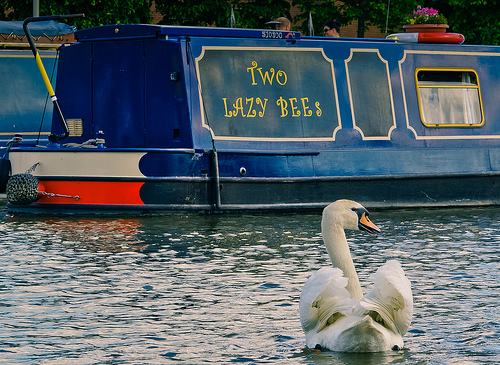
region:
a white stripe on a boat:
[5, 145, 157, 171]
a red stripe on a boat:
[14, 179, 155, 202]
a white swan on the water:
[267, 187, 428, 354]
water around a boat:
[1, 214, 498, 362]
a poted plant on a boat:
[402, 7, 448, 32]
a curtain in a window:
[420, 79, 493, 124]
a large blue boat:
[5, 13, 498, 215]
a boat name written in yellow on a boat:
[216, 57, 329, 128]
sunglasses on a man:
[320, 26, 331, 33]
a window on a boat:
[409, 62, 489, 133]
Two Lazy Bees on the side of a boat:
[216, 57, 322, 131]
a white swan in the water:
[281, 182, 417, 354]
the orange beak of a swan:
[358, 210, 378, 235]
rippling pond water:
[24, 235, 303, 363]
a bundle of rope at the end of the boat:
[6, 154, 58, 211]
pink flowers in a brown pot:
[393, 2, 453, 36]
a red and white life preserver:
[393, 27, 465, 44]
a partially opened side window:
[413, 67, 485, 135]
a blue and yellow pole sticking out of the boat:
[12, 5, 103, 153]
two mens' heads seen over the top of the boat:
[270, 10, 350, 38]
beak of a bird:
[364, 205, 367, 221]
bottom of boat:
[184, 194, 200, 204]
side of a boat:
[419, 177, 428, 190]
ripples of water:
[200, 309, 219, 334]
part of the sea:
[121, 279, 139, 286]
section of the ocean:
[116, 266, 128, 269]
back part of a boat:
[81, 177, 93, 240]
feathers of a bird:
[387, 255, 394, 281]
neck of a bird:
[334, 245, 346, 273]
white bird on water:
[336, 275, 347, 279]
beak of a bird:
[370, 217, 371, 222]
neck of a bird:
[340, 251, 349, 282]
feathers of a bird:
[380, 280, 385, 292]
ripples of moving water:
[179, 342, 189, 352]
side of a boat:
[251, 185, 261, 196]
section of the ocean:
[147, 276, 157, 287]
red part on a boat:
[123, 181, 128, 187]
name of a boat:
[281, 70, 287, 82]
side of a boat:
[358, 180, 393, 201]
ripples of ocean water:
[228, 314, 250, 338]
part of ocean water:
[168, 283, 198, 308]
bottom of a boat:
[176, 195, 193, 202]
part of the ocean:
[210, 280, 245, 328]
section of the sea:
[158, 285, 173, 296]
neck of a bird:
[337, 241, 347, 263]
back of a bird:
[355, 295, 370, 320]